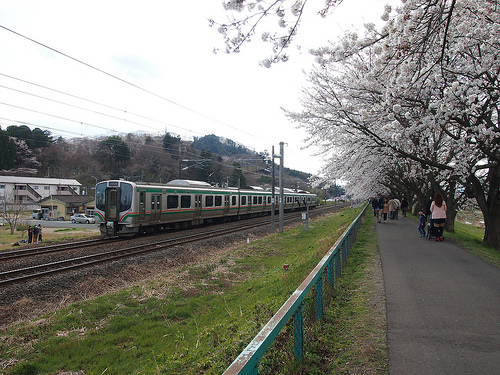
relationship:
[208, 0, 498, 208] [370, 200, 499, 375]
cherry blossom along path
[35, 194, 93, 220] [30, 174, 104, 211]
building with roof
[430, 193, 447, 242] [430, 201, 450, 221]
lady in blazer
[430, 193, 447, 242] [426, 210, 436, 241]
lady pushing baby stroller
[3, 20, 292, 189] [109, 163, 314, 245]
lines for train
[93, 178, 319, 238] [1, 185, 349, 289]
passenger train on tracks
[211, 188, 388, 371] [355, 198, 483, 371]
fence beside path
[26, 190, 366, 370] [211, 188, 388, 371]
grass beside fence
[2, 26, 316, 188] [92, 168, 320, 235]
power lines above train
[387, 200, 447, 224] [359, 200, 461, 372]
people on path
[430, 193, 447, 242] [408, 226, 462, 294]
lady wearing shoes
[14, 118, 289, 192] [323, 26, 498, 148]
trees with flowers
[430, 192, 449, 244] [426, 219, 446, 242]
lady pushing baby stroller